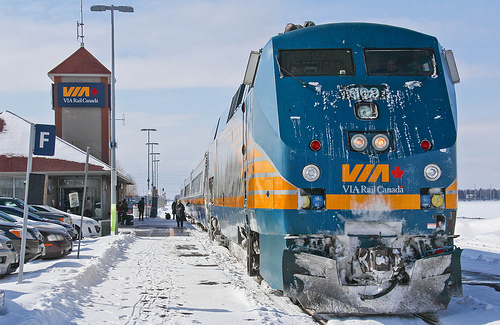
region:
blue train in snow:
[222, 13, 460, 311]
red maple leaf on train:
[387, 157, 409, 184]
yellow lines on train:
[246, 145, 286, 210]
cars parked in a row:
[3, 187, 107, 264]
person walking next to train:
[171, 196, 189, 230]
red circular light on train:
[308, 133, 327, 157]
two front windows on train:
[268, 42, 440, 87]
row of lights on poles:
[134, 121, 167, 190]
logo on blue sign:
[58, 82, 100, 107]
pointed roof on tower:
[55, 43, 110, 75]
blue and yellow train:
[187, 18, 467, 322]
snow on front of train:
[342, 192, 399, 232]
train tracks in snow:
[395, 308, 452, 323]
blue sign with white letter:
[26, 119, 63, 166]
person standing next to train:
[170, 193, 188, 231]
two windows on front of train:
[271, 40, 442, 85]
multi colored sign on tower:
[47, 82, 109, 109]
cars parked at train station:
[5, 191, 109, 259]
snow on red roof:
[9, 126, 84, 169]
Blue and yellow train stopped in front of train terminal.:
[206, 18, 475, 324]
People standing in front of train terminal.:
[113, 186, 201, 242]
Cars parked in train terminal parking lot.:
[1, 191, 102, 276]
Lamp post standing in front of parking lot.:
[89, 3, 133, 243]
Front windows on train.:
[277, 46, 440, 93]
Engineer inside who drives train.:
[368, 49, 415, 76]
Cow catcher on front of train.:
[287, 239, 472, 321]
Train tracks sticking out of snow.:
[302, 308, 447, 323]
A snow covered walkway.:
[111, 229, 227, 323]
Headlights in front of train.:
[292, 156, 444, 183]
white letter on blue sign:
[31, 120, 61, 161]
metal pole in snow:
[12, 164, 39, 290]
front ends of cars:
[4, 216, 106, 264]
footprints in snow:
[140, 255, 192, 318]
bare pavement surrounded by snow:
[140, 223, 190, 241]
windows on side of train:
[182, 169, 207, 197]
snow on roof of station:
[63, 146, 85, 166]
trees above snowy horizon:
[461, 183, 498, 206]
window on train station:
[2, 173, 27, 205]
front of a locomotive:
[267, 22, 460, 323]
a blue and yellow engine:
[272, 20, 463, 318]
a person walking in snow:
[170, 192, 190, 233]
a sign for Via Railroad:
[50, 82, 115, 107]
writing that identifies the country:
[334, 162, 410, 211]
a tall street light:
[84, 2, 141, 236]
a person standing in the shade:
[135, 189, 150, 227]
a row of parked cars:
[1, 190, 98, 279]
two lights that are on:
[337, 127, 400, 154]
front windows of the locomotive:
[273, 43, 441, 90]